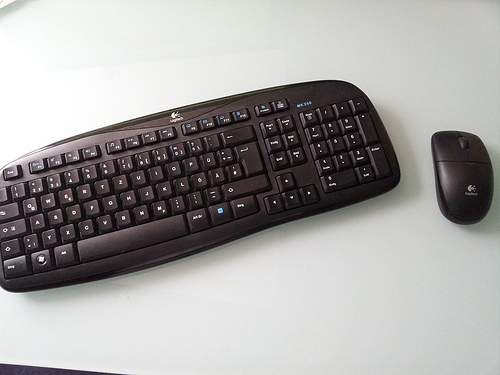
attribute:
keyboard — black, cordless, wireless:
[0, 77, 404, 285]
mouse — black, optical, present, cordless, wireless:
[427, 124, 497, 230]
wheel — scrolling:
[455, 134, 471, 149]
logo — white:
[461, 179, 481, 201]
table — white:
[40, 8, 463, 65]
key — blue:
[207, 201, 231, 223]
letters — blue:
[296, 96, 313, 111]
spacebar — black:
[75, 210, 192, 261]